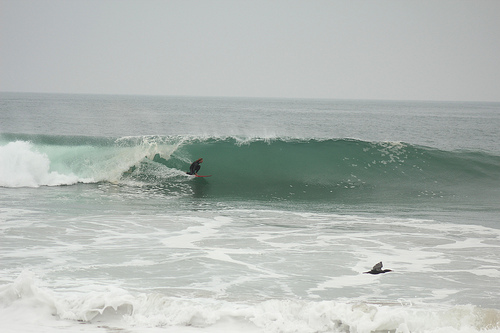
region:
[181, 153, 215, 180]
a surfer riding the waves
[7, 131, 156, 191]
a white wave crashing in the ocean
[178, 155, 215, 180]
a surfer crouching on the board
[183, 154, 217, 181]
a male surfer wearing a black wetsuit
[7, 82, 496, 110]
the vast horizon in the distance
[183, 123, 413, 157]
the upper crest of a wave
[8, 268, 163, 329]
the white foam lapping in the water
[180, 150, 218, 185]
the orange surfboard the person is using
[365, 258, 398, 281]
an unknown object floating in the water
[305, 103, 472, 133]
the rippling water in the ocean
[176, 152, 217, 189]
a surfer riding a wave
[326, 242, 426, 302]
a bird flying above the water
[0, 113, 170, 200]
a wave crashing down on itself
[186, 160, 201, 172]
the surfer's black wetsuit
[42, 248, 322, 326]
ocean foam on the water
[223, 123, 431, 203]
a blue wave about to roll over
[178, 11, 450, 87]
grey clouds over the ocean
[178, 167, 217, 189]
the red surfboard the man is riding on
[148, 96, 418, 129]
calm waters behind the waves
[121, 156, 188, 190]
the wake in the water behind the surfer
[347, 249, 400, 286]
bird flying above water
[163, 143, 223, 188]
person surfing in water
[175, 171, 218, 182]
red surfboard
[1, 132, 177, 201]
white wave in ocean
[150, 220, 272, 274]
white ocean froth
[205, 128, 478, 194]
ocean wave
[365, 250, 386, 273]
wing of bird in flight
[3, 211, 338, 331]
ocean water and small waves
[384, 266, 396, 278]
head and beak of bird in flight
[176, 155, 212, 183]
person in black wetsuit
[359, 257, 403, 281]
dark colored flying bird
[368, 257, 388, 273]
wing of bird over water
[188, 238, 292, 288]
white sea foam of ocean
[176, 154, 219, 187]
person kneeling on surfboard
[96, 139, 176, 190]
curl of crashing ocean wave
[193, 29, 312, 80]
hazy blue gray sky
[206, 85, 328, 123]
calm horizon of ocean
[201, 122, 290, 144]
wind swept water on top of wave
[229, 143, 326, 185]
green curl inside wave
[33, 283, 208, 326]
small wave crashing near shore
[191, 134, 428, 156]
This the crest of the wave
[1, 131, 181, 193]
The wave has crested over here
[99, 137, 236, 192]
This man is shooting the pipeline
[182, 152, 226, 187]
This man is surfing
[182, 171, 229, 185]
A surfboard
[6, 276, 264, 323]
These are called whitecaps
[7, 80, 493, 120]
This is the horizon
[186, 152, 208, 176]
The surfer is wearing a wetsuit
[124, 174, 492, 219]
This is the swell of the wave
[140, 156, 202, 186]
The surfboard leaves a wake behind it